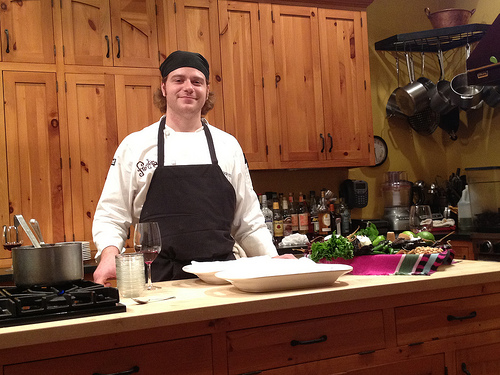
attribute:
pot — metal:
[11, 219, 85, 282]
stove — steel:
[0, 276, 126, 331]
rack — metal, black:
[374, 21, 490, 54]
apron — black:
[139, 115, 235, 279]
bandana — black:
[160, 50, 208, 77]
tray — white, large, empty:
[216, 263, 353, 292]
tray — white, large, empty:
[183, 254, 292, 286]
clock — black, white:
[372, 134, 387, 168]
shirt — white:
[95, 114, 277, 262]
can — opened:
[116, 250, 146, 297]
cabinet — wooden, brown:
[269, 0, 378, 167]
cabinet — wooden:
[58, 0, 163, 69]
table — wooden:
[0, 257, 499, 373]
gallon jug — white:
[458, 184, 482, 227]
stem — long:
[147, 262, 152, 288]